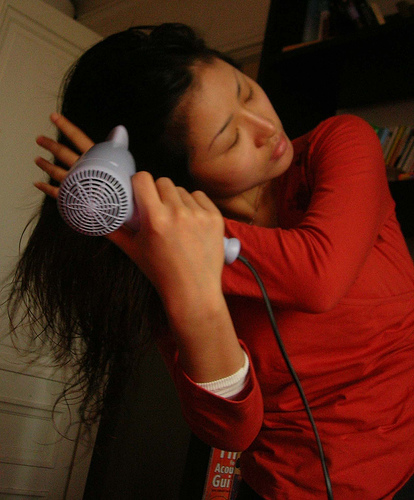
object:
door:
[0, 314, 52, 464]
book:
[200, 447, 242, 499]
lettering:
[212, 462, 234, 487]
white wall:
[190, 2, 255, 21]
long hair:
[0, 20, 242, 471]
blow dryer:
[57, 125, 137, 236]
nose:
[242, 107, 277, 148]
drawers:
[1, 375, 71, 482]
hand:
[107, 171, 224, 316]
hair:
[0, 21, 244, 472]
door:
[8, 24, 67, 429]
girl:
[0, 22, 414, 327]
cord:
[235, 254, 336, 498]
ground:
[363, 75, 396, 111]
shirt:
[157, 113, 414, 500]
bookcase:
[100, 422, 182, 475]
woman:
[0, 22, 414, 499]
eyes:
[227, 80, 252, 151]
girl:
[0, 22, 414, 500]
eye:
[244, 78, 253, 104]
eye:
[226, 127, 240, 151]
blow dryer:
[58, 125, 241, 266]